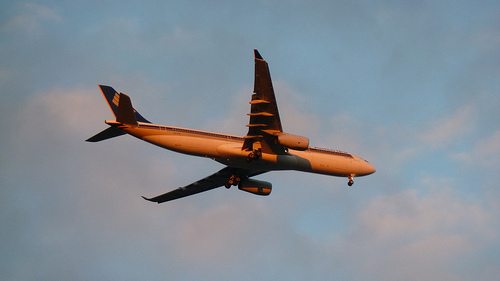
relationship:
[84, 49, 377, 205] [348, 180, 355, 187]
airplane has wheel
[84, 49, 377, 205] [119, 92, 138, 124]
airplane has wing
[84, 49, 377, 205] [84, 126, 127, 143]
airplane has wing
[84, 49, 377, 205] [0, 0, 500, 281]
airplane in sky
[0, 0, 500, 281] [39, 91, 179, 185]
sky has cloud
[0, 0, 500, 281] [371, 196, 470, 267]
sky has cloud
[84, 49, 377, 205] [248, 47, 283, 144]
airplane has wing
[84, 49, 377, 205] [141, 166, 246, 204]
airplane has wing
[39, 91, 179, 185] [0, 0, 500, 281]
cloud in sky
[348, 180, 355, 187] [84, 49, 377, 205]
wheel underneath airplane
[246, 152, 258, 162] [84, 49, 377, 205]
wheel underneath airplane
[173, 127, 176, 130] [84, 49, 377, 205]
window along side of airplane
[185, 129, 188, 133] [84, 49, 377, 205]
window along side of airplane